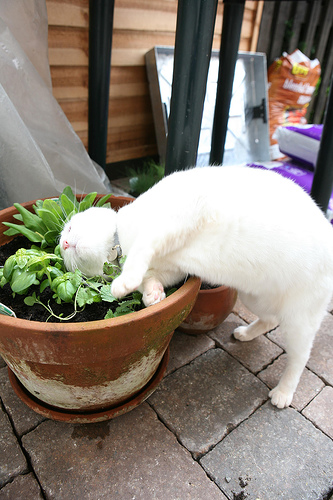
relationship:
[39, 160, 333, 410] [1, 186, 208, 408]
cat leaning on plant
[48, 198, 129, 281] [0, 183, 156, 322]
head in plant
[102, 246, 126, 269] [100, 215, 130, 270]
tag on collar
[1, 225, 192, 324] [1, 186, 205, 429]
soil in pot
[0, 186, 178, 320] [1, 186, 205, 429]
green plant in pot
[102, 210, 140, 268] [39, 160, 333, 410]
collar on cat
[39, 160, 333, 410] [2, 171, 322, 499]
cat on sidewalk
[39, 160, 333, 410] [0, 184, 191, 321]
cat in cotta planter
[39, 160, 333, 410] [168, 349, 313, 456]
cat on bricks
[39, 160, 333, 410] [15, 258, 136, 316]
cat on plant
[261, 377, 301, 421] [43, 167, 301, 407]
foot of a cat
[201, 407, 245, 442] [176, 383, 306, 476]
space between tiles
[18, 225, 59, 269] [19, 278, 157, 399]
green plant in a brown planter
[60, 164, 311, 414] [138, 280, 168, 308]
cat has forepaw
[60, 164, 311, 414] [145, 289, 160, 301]
cat has toes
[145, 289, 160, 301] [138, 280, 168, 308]
toes on forepaw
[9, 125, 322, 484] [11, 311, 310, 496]
patio has bricks